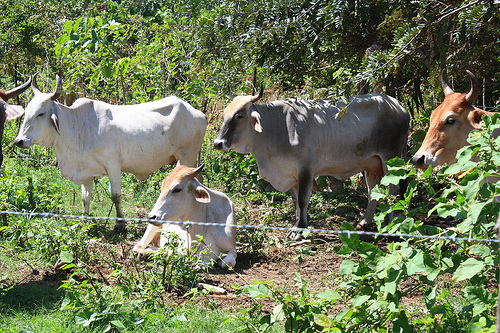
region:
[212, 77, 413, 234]
Bull standing on the ground.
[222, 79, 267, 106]
Horns on the bull.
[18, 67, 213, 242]
White bull standing on the ground.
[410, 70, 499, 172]
Brown bull behind the bush.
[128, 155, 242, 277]
Bull laying on the ground.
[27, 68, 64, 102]
Horns on the bull.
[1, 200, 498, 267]
Barbed wire in the forefront.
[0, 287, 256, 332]
Green grass on the ground.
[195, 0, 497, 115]
Tree in the background.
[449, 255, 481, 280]
Green leaf on the bush.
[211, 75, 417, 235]
this is a cow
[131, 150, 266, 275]
this is a cow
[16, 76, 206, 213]
this is a cow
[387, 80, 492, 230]
this is a cow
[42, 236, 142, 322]
this is a plant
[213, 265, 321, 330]
this is a plant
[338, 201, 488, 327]
this is a plant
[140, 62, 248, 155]
this is a plant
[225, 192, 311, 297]
this is a plant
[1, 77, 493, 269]
cattle on the ground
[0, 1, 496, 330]
green bushes where cattle is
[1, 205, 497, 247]
metal wire fence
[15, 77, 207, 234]
white cow standing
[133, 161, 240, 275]
brown and white cow lying in the floor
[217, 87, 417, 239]
black and white cow standing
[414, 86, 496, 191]
light brown cow behind bushes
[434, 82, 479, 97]
little chunks of brown cow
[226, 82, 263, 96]
little chunks of black and white cow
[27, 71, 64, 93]
big chunks of white cow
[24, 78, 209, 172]
a cow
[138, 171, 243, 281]
the cow is laying down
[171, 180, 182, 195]
eye of the cow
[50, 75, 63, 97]
the cow has a horn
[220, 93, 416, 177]
the cow is standing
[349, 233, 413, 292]
the leaves are green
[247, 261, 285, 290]
the dirt on the ground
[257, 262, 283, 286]
the dirt is brown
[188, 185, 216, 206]
the cows ear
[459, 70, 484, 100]
the cows horn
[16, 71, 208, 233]
white bull standing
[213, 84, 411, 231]
gray cow behind a bull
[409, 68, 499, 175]
head of a maroon bull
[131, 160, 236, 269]
white and maroon cow laying on the ground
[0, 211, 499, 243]
wire going through a field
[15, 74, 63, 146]
head of a white bull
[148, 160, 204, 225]
head of a white and maroon cow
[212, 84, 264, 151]
head of a gray cow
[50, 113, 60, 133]
ear of a white bull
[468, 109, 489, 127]
ear of a maroon bull